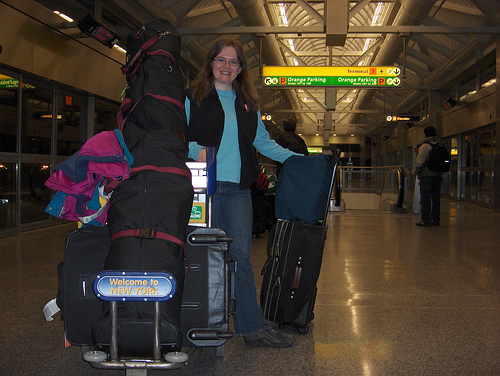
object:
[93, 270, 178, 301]
sign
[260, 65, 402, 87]
sign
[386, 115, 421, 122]
sign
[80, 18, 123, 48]
sign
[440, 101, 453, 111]
sign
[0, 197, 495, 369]
floor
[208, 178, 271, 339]
jeans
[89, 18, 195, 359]
bag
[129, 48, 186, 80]
strap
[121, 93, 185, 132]
strap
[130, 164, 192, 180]
strap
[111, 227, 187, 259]
strap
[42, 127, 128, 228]
coat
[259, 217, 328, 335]
luggage bag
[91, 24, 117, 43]
display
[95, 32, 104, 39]
red lights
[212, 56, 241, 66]
glasses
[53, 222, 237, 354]
luggage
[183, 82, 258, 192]
vest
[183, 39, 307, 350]
grinning lady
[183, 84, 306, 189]
shirt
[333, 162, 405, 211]
escalator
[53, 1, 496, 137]
roof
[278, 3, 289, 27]
lights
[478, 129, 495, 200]
door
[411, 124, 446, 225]
man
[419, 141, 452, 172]
backpack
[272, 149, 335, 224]
bag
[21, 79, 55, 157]
grass windows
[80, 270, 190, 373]
trolley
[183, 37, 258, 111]
hair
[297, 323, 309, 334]
wheels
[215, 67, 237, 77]
grin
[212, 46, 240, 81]
face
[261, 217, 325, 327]
side